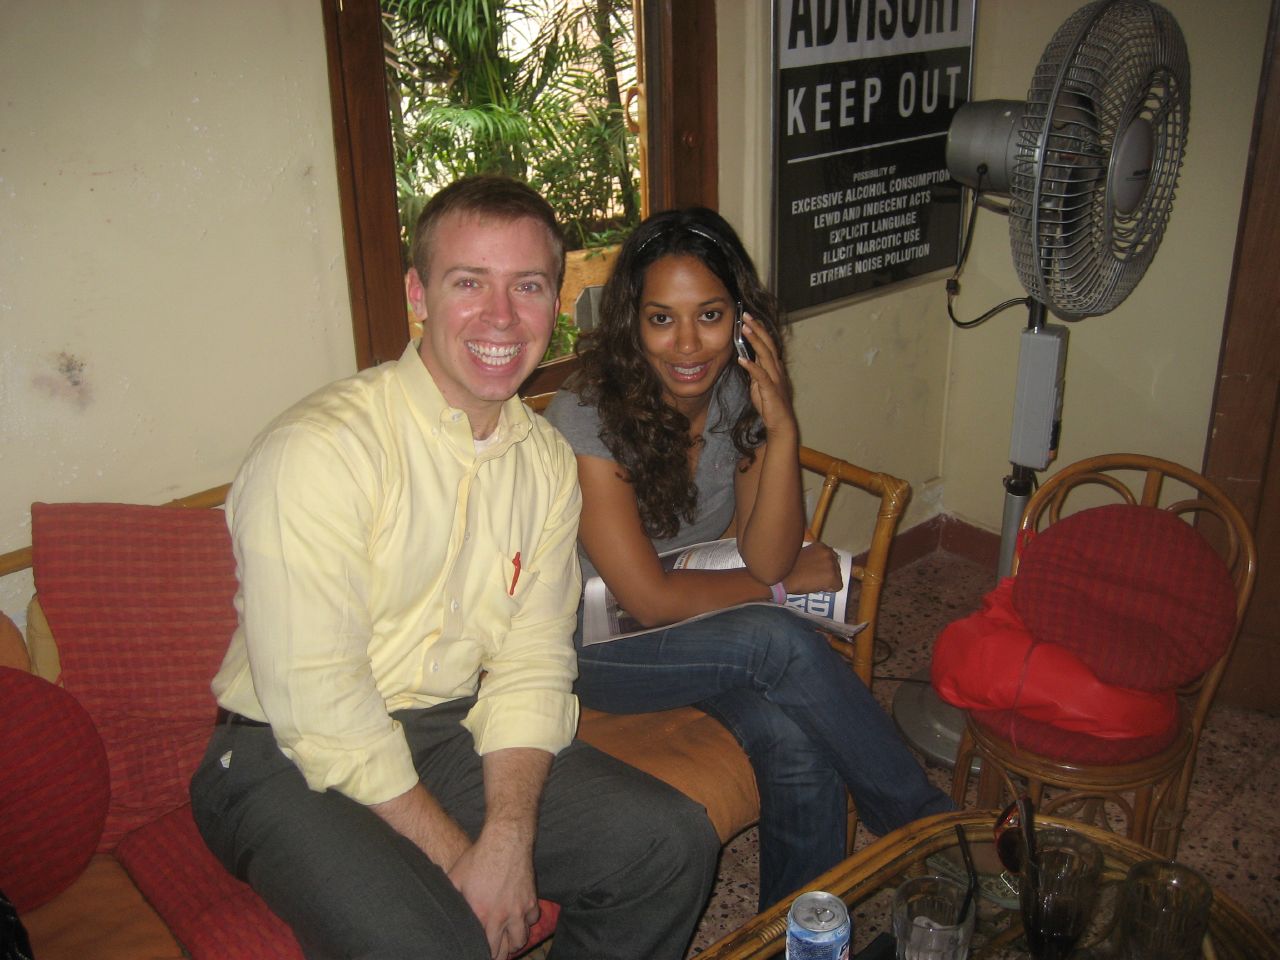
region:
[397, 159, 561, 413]
a caucasian male smiling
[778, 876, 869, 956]
a canned drink on a table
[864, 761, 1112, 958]
glass tumblers with straws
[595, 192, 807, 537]
an african american lady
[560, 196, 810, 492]
a female holding her mobile phone next to her ear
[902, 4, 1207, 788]
an electric fan on the floor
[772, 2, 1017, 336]
a poster hanging on the wall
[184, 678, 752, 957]
Man wearing pants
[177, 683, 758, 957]
Man is wearing pants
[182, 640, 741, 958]
Man wearing gray pants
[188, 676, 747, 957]
Man is wearing gray pants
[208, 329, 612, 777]
Man wearing a yellow shirt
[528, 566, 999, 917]
Woman is wearing blue jeans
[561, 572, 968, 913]
Woman wearing blue jeans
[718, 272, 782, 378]
Woman holding a cell phone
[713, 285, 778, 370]
Woman is holding a cell phone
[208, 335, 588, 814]
Man's yellow button up shirt with a red pen in the pocket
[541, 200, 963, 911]
Dark skinned woman with a cell phone up to her ear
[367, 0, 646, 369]
Tropical greenery outside a window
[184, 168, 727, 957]
Fair skinned man smiling really big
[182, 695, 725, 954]
Grey colored man's dress pants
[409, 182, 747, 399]
Two faces are smiling.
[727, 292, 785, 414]
A hand is holding a cell phone.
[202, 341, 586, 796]
A man is wearing a yellow shirt.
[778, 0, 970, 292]
A black and white sign has a warning on it.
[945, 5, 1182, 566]
A silver fan is on a stand.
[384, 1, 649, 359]
Green leaves are in the window.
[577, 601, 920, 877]
The legs are crossed and in blue pants.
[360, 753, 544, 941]
The man has his hands clasped.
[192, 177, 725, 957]
A person sitting down.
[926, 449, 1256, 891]
A chair that you sit in.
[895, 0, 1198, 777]
A fan used for cooling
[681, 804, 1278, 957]
A normal table.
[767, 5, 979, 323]
A picture in a frame.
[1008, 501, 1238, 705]
A cushion on a seat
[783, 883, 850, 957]
aluminum beverage can on the table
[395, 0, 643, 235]
palm fronds show through a window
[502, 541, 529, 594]
red pen hooked onto a pocket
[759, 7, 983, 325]
framed black and white "Keep Out" sign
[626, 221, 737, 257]
a plastic head band to hold back hair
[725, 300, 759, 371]
cell phone held up to left ear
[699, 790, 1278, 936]
glass top rattan coffee table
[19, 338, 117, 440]
dirty smudge on a pastel yellow wall